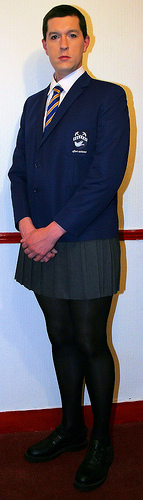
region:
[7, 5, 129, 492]
the man standing in a skirt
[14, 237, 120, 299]
the skirt on the man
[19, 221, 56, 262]
the two hands on the man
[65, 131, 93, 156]
the pocket on the man's jacket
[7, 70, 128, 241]
the jacket on the man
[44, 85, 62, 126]
the tie on the man's neck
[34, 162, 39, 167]
the button on the man's jacket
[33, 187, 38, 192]
the button on the man's jacket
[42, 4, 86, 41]
the dark hair on the man's head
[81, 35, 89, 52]
the ear on the man's head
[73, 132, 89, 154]
WHITE LOGO ON THE POCKET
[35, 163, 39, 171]
BLUE BUTTON ON THE COAT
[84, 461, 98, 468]
PERSON WEARING BLACK SHOES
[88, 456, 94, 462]
SHOE LACE ON THE SHOE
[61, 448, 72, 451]
RUBBER BOTTOM ON THE SHOE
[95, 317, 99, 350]
PERSON WEARING BLACK STOCKINGS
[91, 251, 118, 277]
PERSON IN PLEATED SKIRT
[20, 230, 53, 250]
HANDS FOLDED ON TOP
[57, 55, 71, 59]
SMALL RED LIPS GLOWING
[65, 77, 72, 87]
WHITE COLLAR SHIRT MAN WEARING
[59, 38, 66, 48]
the nose of a person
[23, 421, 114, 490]
black shoes of a person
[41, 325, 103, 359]
the knees of a person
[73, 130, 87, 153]
a badge on a jacket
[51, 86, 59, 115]
a stripped tie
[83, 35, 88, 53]
the ear of a person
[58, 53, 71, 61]
the mouth of a person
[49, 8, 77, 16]
the black hair of a person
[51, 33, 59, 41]
the eye of a person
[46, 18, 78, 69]
the face of a person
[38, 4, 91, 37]
The man has dark hair.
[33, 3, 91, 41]
The mans hair is black.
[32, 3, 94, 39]
The mans hair is short.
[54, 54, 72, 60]
The man is wearing lipstick.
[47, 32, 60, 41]
The man has a dark eye.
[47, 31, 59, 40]
The mans eye is open.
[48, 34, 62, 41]
The mans eye is brown.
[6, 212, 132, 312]
The man is wearing a gray skirt.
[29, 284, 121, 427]
The man is wearing black stockings.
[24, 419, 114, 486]
The man is wearing black shoes.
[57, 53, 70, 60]
Closed lips that are red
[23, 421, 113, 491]
Two black dress shoes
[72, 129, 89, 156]
Patch on a blue blazer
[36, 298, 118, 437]
Black panty hose on legs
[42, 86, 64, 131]
Blue and gold tie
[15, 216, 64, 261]
Hands that are held together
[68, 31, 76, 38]
Rey eye on man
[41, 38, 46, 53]
Left ear on mans head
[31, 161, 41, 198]
Two buttons on the blue jacket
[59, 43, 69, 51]
Nose on the mans face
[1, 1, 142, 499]
Close-up of man in androgynous attire.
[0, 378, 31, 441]
Red carpeting and blue wall, surrounding man.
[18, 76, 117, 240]
Torso with white, collared shirt, striped tie and uniform jacket.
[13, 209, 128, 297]
Folded hands, fronting short, grey, pleated skirt.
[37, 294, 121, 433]
Legs in black stockings.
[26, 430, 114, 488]
Feet in black loafers.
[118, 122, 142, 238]
Shadow and red stripe on wall.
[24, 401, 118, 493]
pair of boots on man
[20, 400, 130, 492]
pair of boots on man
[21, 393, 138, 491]
pair of boots on man